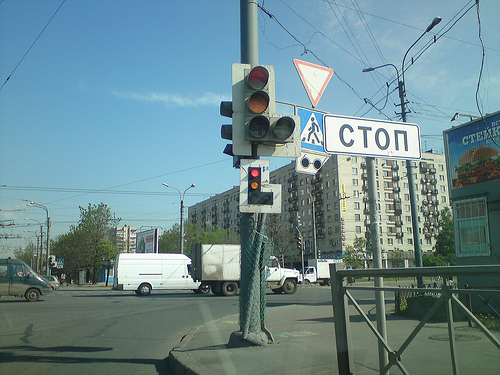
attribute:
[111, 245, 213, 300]
van — white, black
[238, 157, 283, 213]
stop light —  stop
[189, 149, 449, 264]
building — tan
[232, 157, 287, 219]
traffic light — minature lit up traffic 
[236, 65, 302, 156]
stop light — stop 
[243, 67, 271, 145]
traffic light — lit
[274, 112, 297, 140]
traffic light — lit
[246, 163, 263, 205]
traffic light — lit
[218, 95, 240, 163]
traffic light — lit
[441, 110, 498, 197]
sign — large hamburger, blue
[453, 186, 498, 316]
building — grey 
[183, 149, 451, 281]
building — wide gray 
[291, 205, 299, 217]
terrace — small black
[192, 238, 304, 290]
truck — white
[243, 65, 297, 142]
traffic light — unlit traffic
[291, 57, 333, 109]
sign — white caution , red 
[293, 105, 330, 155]
sign — small, blue, white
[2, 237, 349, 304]
vehicles — line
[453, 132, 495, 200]
hamburger — pictured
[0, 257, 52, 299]
van — green, driving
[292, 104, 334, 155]
sign — walking, attached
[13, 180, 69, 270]
lamp posts — line 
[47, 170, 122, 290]
trees — line 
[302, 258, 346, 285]
truck — background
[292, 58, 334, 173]
sign — triangular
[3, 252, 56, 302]
mini van — green, tan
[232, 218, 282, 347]
fencing — wire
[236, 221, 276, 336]
wire — green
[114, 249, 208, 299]
mini van — white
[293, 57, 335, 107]
yield sign — white yield , red  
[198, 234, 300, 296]
truck — white, gray, black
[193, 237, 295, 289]
truck — box , driving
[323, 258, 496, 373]
gate — metal 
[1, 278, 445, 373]
street —  paved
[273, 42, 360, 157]
sign — street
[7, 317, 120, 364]
shadows — dark